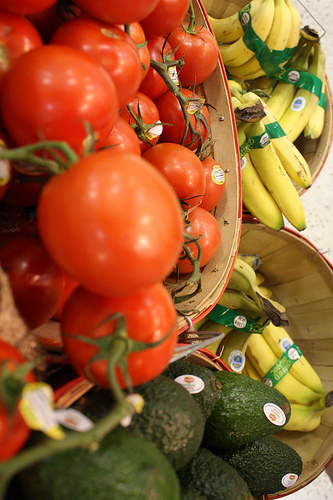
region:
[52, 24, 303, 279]
the view is a fruit basket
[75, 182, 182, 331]
the tomatoes are rippen red in color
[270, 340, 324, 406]
the bananas are ripen yellow in color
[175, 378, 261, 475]
the tomaaaaaaatoes are green in color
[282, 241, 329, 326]
the basket is brown in color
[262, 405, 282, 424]
the sticker is white in color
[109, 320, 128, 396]
the tomato part is green in color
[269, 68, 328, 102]
the stripe is green in color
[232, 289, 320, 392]
the bananas are in bundles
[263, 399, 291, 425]
words on sticker are writen in orange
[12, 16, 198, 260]
these are the tomatoes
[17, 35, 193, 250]
the tomatoes are ripe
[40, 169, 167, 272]
the tomato is red in color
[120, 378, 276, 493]
these are the avocados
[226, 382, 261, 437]
the avocado is green in color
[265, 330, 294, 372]
this is a bunch of banana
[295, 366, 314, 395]
the banana are yellow in color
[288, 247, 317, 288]
this is a tray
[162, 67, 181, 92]
this is the stalk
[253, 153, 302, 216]
the banana are big in size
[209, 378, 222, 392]
a stem piece on an avocado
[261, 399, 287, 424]
a white oval sticker on an avocado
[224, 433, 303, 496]
a dark green avocado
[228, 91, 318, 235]
a bunch of yellow bananas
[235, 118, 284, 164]
green tape around yellow bananas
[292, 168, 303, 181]
a brown bruise on a banana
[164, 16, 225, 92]
a tomato n a basket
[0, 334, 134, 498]
a long stem on a tomato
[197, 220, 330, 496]
a basket with red trim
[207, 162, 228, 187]
a yellow and white sticker on a tomato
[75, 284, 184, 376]
RED TOMATO IN BASKET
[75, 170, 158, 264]
RED TOMATO IN BASKET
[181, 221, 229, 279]
RED TOMATO IN BASKET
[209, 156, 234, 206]
RED TOMATO IN BASKET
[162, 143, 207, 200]
RED TOMATO IN BASKET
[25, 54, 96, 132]
RED TOMATO IN BASKET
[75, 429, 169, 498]
GREEN AVACADO IN BASKET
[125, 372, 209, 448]
GREEN AVACADO IN BASKET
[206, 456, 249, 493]
GREEN AVACADO IN BASKET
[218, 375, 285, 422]
GREEN AVACADO IN BASKET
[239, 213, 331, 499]
bananas inside a bushel basket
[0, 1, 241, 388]
tomatoes inside a bushel basket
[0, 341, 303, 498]
avocados inside a bushel basket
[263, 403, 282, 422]
white oval sticker on top of an avacado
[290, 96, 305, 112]
white sticker on top of a banana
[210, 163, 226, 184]
sticker on top of a tomato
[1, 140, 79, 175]
green stem attached to a tomato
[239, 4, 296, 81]
green tape wrapped around a banana bunch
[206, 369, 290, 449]
avacado is green and bumpy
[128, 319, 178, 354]
narrow green leaf